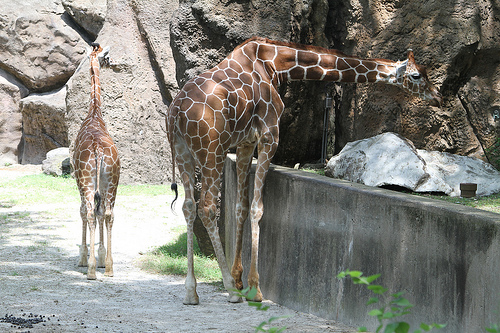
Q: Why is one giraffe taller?
A: It's a parent.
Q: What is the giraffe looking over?
A: Edge.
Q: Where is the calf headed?
A: Rock wall.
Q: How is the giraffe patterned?
A: Spotted.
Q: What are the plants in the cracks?
A: Weeds.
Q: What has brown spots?
A: Giraffe.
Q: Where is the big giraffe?
A: In back.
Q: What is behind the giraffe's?
A: Their tails.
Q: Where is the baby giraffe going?
A: Towards the rocks.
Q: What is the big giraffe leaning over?
A: Cement wall.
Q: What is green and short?
A: The grass.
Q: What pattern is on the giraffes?
A: Spots.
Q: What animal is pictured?
A: Giraffe.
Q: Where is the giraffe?
A: In pen.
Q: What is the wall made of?
A: Rock.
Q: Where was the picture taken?
A: Zoo.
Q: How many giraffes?
A: Two.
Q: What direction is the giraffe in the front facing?
A: To the right.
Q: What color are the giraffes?
A: Brown and white.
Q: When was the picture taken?
A: During daytime.